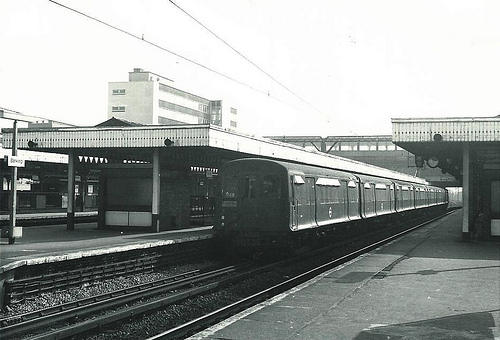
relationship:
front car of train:
[211, 155, 362, 257] [211, 156, 449, 258]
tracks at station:
[4, 244, 304, 340] [0, 67, 499, 338]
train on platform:
[203, 158, 449, 259] [6, 227, 226, 274]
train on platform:
[203, 158, 449, 259] [2, 202, 98, 225]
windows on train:
[293, 175, 446, 201] [213, 157, 448, 244]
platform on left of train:
[184, 232, 499, 334] [211, 156, 449, 258]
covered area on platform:
[6, 127, 428, 230] [210, 157, 455, 248]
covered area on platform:
[383, 116, 498, 238] [391, 116, 499, 238]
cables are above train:
[192, 8, 239, 149] [209, 152, 460, 275]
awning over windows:
[292, 173, 452, 195] [294, 185, 446, 203]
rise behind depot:
[118, 62, 233, 139] [3, 126, 433, 229]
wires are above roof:
[10, 0, 332, 90] [1, 123, 498, 223]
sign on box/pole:
[5, 153, 26, 168] [9, 123, 17, 245]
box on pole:
[0, 164, 35, 195] [6, 117, 22, 245]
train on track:
[186, 145, 448, 248] [14, 242, 301, 338]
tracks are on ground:
[4, 256, 254, 337] [0, 240, 311, 335]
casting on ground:
[332, 262, 499, 338] [180, 208, 497, 338]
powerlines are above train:
[42, 0, 367, 127] [204, 153, 466, 246]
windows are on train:
[372, 180, 392, 203] [211, 156, 449, 258]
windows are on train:
[361, 183, 373, 203] [211, 156, 449, 258]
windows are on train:
[315, 176, 340, 204] [211, 156, 449, 258]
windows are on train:
[346, 181, 358, 203] [211, 156, 449, 258]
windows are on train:
[291, 175, 317, 232] [211, 156, 449, 258]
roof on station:
[4, 120, 418, 177] [2, 113, 437, 275]